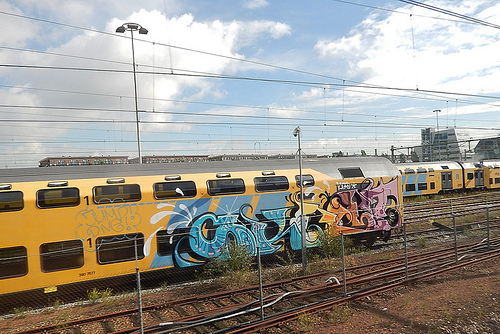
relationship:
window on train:
[205, 177, 245, 195] [0, 153, 404, 310]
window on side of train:
[88, 173, 140, 213] [0, 153, 404, 310]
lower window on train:
[94, 231, 143, 264] [2, 157, 402, 294]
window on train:
[144, 180, 198, 198] [13, 155, 399, 275]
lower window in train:
[94, 231, 143, 264] [2, 157, 402, 294]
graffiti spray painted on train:
[144, 175, 400, 271] [0, 153, 404, 310]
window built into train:
[33, 187, 81, 208] [0, 153, 404, 310]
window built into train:
[88, 173, 140, 213] [0, 153, 404, 310]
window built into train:
[144, 180, 198, 198] [0, 153, 404, 310]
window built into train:
[205, 177, 245, 195] [0, 153, 404, 310]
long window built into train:
[253, 175, 290, 193] [0, 153, 404, 310]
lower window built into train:
[0, 243, 32, 279] [0, 153, 404, 310]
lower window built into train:
[38, 236, 87, 269] [0, 153, 404, 310]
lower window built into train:
[95, 233, 144, 262] [0, 153, 404, 310]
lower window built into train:
[153, 224, 192, 253] [0, 153, 404, 310]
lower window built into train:
[415, 180, 429, 189] [0, 153, 404, 310]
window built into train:
[417, 179, 429, 192] [395, 155, 498, 202]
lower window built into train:
[38, 238, 85, 272] [2, 157, 402, 294]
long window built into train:
[253, 175, 290, 193] [2, 157, 402, 294]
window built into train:
[33, 187, 81, 208] [2, 157, 402, 294]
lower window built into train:
[94, 231, 143, 264] [2, 157, 402, 294]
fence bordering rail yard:
[211, 211, 498, 296] [1, 160, 481, 329]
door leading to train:
[440, 170, 448, 190] [394, 158, 498, 199]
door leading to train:
[441, 171, 453, 190] [394, 158, 498, 199]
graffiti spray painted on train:
[76, 195, 143, 251] [26, 127, 424, 319]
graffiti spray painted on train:
[144, 175, 400, 271] [2, 157, 402, 294]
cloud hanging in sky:
[18, 8, 245, 136] [1, 2, 484, 167]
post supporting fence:
[251, 242, 266, 322] [70, 210, 494, 330]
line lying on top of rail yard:
[153, 290, 311, 332] [1, 244, 480, 334]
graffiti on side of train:
[168, 185, 410, 251] [5, 175, 169, 272]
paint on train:
[0, 167, 360, 296] [56, 143, 427, 289]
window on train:
[205, 177, 245, 195] [2, 157, 402, 294]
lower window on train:
[417, 182, 427, 190] [26, 89, 458, 311]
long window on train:
[244, 177, 307, 198] [0, 153, 404, 310]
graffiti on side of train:
[144, 175, 400, 271] [0, 153, 404, 310]